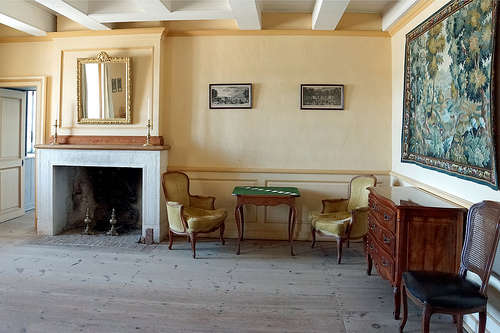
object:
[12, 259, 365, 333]
rug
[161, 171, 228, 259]
chair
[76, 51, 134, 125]
frame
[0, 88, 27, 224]
door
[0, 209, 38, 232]
hallway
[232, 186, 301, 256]
table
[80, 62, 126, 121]
mirror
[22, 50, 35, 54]
rafters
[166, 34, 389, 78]
wall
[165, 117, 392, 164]
wall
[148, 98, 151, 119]
candle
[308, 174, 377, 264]
chairs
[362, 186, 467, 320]
chest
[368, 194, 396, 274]
drawers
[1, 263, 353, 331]
flooring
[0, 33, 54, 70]
wall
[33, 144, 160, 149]
mantle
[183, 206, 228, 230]
seat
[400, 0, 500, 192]
rug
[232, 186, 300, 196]
top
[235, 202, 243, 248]
leg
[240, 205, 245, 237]
leg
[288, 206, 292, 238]
leg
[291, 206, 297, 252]
leg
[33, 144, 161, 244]
fireplace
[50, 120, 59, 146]
candelabrum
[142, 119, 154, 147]
candelabrum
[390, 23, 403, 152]
wall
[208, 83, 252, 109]
frame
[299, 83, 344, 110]
frame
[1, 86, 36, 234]
doorway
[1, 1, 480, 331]
room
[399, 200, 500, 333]
chair